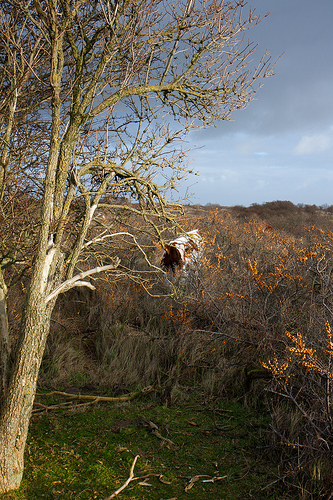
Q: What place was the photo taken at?
A: It was taken at the forest.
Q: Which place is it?
A: It is a forest.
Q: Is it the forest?
A: Yes, it is the forest.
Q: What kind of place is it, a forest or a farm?
A: It is a forest.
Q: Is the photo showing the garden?
A: No, the picture is showing the forest.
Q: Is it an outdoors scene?
A: Yes, it is outdoors.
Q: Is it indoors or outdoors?
A: It is outdoors.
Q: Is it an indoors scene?
A: No, it is outdoors.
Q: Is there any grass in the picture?
A: Yes, there is grass.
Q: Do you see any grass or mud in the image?
A: Yes, there is grass.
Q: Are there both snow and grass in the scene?
A: No, there is grass but no snow.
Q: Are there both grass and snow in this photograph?
A: No, there is grass but no snow.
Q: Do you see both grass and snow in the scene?
A: No, there is grass but no snow.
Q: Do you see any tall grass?
A: Yes, there is tall grass.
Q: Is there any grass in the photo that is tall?
A: Yes, there is grass that is tall.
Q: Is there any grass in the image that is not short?
A: Yes, there is tall grass.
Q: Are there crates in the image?
A: No, there are no crates.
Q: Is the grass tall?
A: Yes, the grass is tall.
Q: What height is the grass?
A: The grass is tall.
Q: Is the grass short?
A: No, the grass is tall.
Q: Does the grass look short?
A: No, the grass is tall.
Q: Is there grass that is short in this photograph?
A: No, there is grass but it is tall.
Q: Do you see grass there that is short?
A: No, there is grass but it is tall.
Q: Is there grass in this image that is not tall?
A: No, there is grass but it is tall.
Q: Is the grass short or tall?
A: The grass is tall.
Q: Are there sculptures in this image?
A: No, there are no sculptures.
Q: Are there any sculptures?
A: No, there are no sculptures.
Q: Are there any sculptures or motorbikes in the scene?
A: No, there are no sculptures or motorbikes.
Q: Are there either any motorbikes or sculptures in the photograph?
A: No, there are no sculptures or motorbikes.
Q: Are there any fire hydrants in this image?
A: No, there are no fire hydrants.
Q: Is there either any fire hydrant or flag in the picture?
A: No, there are no fire hydrants or flags.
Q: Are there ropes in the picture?
A: No, there are no ropes.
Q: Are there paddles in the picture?
A: No, there are no paddles.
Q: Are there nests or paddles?
A: No, there are no paddles or nests.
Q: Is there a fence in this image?
A: No, there are no fences.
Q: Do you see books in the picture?
A: No, there are no books.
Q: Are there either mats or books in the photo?
A: No, there are no books or mats.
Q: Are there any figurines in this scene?
A: No, there are no figurines.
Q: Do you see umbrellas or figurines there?
A: No, there are no figurines or umbrellas.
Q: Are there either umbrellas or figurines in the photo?
A: No, there are no figurines or umbrellas.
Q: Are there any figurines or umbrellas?
A: No, there are no figurines or umbrellas.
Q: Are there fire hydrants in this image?
A: No, there are no fire hydrants.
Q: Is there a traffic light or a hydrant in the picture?
A: No, there are no fire hydrants or traffic lights.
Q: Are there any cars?
A: No, there are no cars.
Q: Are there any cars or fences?
A: No, there are no cars or fences.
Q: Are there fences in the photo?
A: No, there are no fences.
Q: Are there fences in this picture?
A: No, there are no fences.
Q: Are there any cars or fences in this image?
A: No, there are no fences or cars.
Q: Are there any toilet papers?
A: No, there are no toilet papers.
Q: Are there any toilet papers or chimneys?
A: No, there are no toilet papers or chimneys.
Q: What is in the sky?
A: The clouds are in the sky.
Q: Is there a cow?
A: Yes, there is a cow.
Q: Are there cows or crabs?
A: Yes, there is a cow.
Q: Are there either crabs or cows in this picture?
A: Yes, there is a cow.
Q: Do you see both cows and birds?
A: No, there is a cow but no birds.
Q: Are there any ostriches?
A: No, there are no ostriches.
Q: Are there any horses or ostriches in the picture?
A: No, there are no ostriches or horses.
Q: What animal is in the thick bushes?
A: The cow is in the shrubs.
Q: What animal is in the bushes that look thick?
A: The animal is a cow.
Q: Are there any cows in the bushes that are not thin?
A: Yes, there is a cow in the shrubs.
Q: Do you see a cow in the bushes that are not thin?
A: Yes, there is a cow in the shrubs.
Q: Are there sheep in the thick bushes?
A: No, there is a cow in the bushes.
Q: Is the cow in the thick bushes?
A: Yes, the cow is in the shrubs.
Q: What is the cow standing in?
A: The cow is standing in the bush.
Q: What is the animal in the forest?
A: The animal is a cow.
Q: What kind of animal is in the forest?
A: The animal is a cow.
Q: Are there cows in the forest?
A: Yes, there is a cow in the forest.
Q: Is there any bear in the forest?
A: No, there is a cow in the forest.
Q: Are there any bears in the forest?
A: No, there is a cow in the forest.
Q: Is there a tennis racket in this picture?
A: No, there are no rackets.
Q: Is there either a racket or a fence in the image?
A: No, there are no rackets or fences.